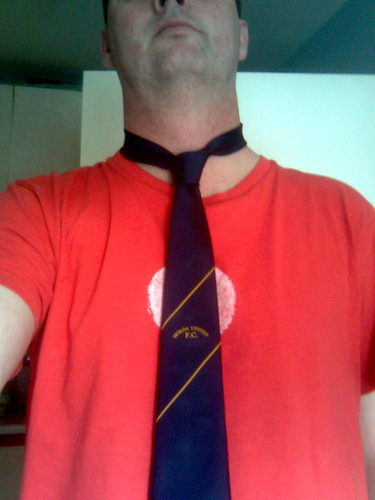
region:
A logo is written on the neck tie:
[166, 321, 216, 342]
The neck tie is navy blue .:
[118, 121, 250, 498]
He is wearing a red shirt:
[3, 199, 373, 496]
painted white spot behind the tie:
[137, 255, 241, 332]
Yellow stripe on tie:
[157, 341, 221, 422]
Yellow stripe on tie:
[162, 263, 217, 327]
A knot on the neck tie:
[165, 151, 214, 187]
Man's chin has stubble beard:
[120, 72, 235, 100]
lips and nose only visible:
[147, 0, 202, 42]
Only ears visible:
[238, 15, 251, 63]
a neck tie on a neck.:
[112, 118, 251, 240]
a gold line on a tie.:
[148, 338, 235, 422]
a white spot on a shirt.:
[139, 258, 245, 337]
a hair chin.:
[146, 40, 207, 100]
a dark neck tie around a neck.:
[120, 118, 249, 498]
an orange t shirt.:
[0, 150, 373, 499]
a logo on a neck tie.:
[172, 320, 214, 346]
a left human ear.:
[228, 15, 255, 67]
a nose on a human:
[151, 0, 192, 19]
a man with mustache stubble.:
[143, 4, 211, 46]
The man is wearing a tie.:
[120, 137, 259, 452]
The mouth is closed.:
[112, 5, 227, 62]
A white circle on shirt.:
[129, 255, 249, 333]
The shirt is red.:
[10, 183, 360, 425]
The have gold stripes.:
[148, 276, 237, 394]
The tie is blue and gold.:
[162, 223, 235, 493]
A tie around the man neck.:
[110, 107, 266, 183]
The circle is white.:
[142, 266, 235, 332]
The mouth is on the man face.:
[141, 17, 215, 55]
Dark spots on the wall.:
[8, 53, 93, 99]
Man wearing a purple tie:
[141, 146, 226, 456]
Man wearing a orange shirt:
[51, 156, 374, 352]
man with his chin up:
[146, 22, 252, 95]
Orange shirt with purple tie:
[132, 248, 242, 338]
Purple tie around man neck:
[92, 98, 289, 176]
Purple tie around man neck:
[115, 119, 267, 230]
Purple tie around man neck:
[143, 140, 219, 233]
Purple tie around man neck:
[100, 141, 259, 182]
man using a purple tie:
[121, 108, 260, 179]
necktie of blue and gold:
[109, 111, 262, 494]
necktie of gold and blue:
[110, 107, 249, 494]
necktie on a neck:
[92, 111, 275, 193]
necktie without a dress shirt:
[88, 108, 269, 233]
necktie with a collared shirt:
[108, 105, 260, 209]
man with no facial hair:
[95, 3, 254, 99]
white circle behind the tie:
[131, 242, 245, 351]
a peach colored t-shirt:
[0, 151, 370, 498]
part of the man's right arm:
[0, 268, 48, 398]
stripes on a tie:
[129, 234, 237, 445]